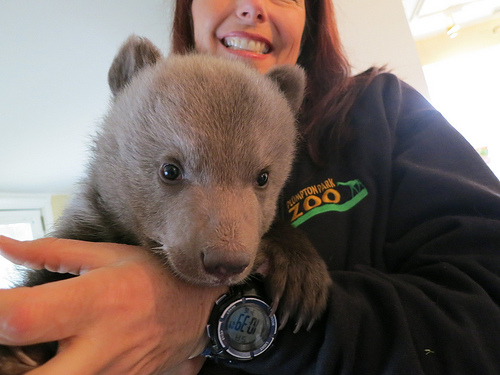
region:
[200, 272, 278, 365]
the watch on the woman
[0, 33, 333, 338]
the young gray bear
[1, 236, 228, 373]
the hand under the bear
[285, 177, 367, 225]
the logo on the shirt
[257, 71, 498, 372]
the woman's shirt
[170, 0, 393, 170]
the hair on the woman's head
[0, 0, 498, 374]
the woman holding the bear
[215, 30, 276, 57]
the smile on the woman's face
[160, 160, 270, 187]
the eyes on the bear's face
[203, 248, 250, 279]
the nose on the bear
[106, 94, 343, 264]
a pupy looking at the camera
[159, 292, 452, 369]
lady has a wath in her hand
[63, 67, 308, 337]
lady is carying a puppy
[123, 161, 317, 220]
the eyes are black in color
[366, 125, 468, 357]
the swater is navy blue in color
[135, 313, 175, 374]
the person is lightskinned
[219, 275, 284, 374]
the watch is black in color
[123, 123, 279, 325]
the pupy is brown in coor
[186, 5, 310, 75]
teeth are white in coor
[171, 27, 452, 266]
the lady is smilling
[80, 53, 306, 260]
this is a bear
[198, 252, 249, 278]
this is the nose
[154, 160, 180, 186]
this is the eye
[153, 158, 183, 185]
the eye is open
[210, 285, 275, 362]
this is a wrist watch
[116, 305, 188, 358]
this is the hand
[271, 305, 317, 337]
these are the claws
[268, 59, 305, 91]
this is the ear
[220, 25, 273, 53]
the lady is smiling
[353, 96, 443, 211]
this is a jacket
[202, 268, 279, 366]
a black wrist watch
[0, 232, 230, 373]
a woman's hand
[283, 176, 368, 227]
zoo logo embroidered on a shirt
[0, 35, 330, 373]
bear cub in a woman's arm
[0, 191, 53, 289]
white glass door and frame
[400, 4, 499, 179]
opening into another room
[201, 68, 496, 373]
black sweatshirt with zoo logo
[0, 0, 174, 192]
white ceiling in room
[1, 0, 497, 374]
zoo staff member holding a bear cub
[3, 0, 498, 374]
woman holding a bear cub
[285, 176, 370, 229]
logo on woman's sweatshirt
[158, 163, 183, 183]
eye of baby bear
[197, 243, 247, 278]
nose of baby bear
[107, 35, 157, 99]
ear on baby bear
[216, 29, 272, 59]
mouth on woman's face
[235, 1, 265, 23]
nose on woman's face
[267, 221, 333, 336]
paw of baby bear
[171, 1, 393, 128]
woman's red hair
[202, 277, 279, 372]
watch on woman's wrist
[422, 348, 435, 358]
piece of lint on woman's sweatshirt